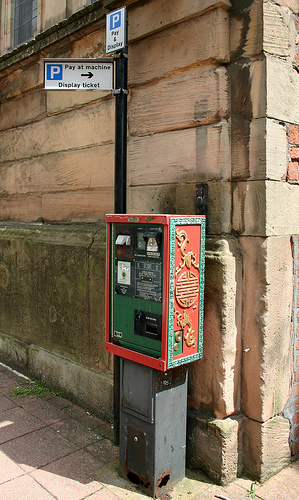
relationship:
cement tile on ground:
[267, 476, 295, 498] [277, 484, 287, 492]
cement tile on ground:
[0, 423, 82, 474] [0, 360, 298, 498]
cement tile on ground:
[0, 423, 82, 474] [5, 400, 111, 496]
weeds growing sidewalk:
[6, 375, 63, 397] [0, 361, 296, 497]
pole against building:
[114, 7, 127, 446] [0, 0, 297, 486]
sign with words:
[103, 3, 126, 54] [106, 28, 121, 51]